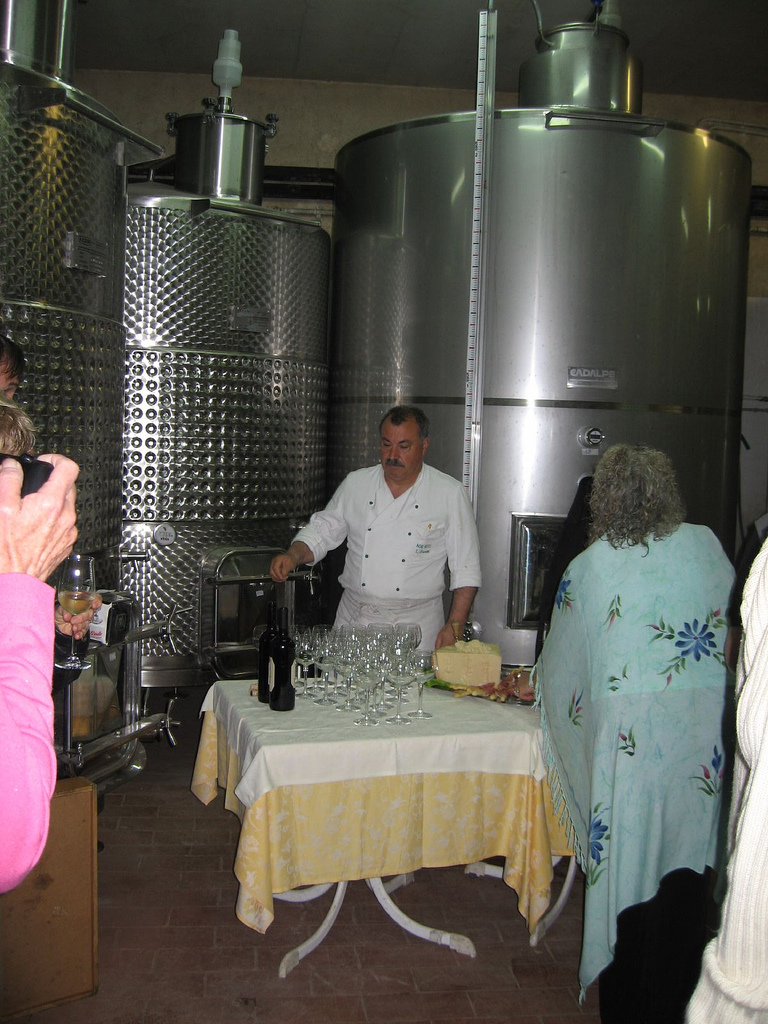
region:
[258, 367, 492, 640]
the man is looking down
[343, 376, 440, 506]
the man has a mustache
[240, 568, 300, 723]
two bottles on the table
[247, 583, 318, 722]
the bottles are dark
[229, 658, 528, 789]
the table cloth is white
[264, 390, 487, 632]
the man is wearing white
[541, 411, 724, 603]
the woman has grey hair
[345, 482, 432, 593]
the buttons are black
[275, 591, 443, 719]
empty glasses on the table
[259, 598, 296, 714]
Two black bottles of wine.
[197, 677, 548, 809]
A top white table cloth.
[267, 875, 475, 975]
White legs of a table under a yellow table cloth.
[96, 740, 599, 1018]
A red brick floor.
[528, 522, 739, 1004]
A blue floral shaw.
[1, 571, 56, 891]
A pink sleeve.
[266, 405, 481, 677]
Grey haired man in white coat and white apron.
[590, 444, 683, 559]
Curly grey hair over a blue shaw.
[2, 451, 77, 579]
A right hand above a pink sleeve.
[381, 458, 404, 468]
A grey mustache on a man.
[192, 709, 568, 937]
the table cloth is yellow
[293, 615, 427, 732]
the glasses are empty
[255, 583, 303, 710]
the bottle are on the table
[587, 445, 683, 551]
the woman has curly hair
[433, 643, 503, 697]
the box is yellow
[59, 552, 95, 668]
the glass has wine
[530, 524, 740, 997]
the woman wears blue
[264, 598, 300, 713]
bottle of wine on the table in the winery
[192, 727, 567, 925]
yellow table cloth on the tasting table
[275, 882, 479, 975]
aluminum legs of the wine tasting table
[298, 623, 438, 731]
wine glasses on a table in the distilery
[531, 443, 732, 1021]
person wearing a blue floral shawl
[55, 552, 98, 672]
a person holding a wine goblet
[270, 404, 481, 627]
wine maker wearing a chef uniform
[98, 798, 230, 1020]
brown tiled floor in the distilery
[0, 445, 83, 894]
person wearing a pink shirt holding a camera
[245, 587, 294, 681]
brown wine bottles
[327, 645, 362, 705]
clear glass on table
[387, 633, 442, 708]
clear glass on table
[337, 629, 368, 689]
clear glass on table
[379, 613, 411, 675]
clear glass on table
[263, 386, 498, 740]
man pointing to wine bottle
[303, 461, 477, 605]
white chef jacket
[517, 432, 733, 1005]
woman wearing blue caftan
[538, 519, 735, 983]
blue floral shawl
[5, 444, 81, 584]
hand holding camera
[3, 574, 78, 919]
pink sleeve of shirt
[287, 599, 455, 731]
wine glasses on table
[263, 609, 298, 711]
wine bottle on table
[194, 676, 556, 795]
white table clothe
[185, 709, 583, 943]
long yellow table cloth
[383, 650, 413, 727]
A vessel made for drinking.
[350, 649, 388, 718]
A vessel made for drinking.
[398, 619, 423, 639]
A vessel made for drinking.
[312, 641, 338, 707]
A vessel made for drinking.